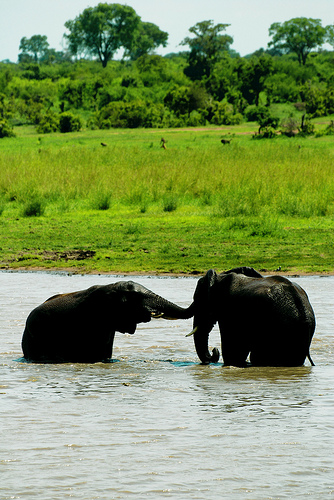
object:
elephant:
[185, 260, 321, 377]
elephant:
[17, 276, 196, 371]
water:
[0, 271, 333, 500]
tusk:
[184, 325, 198, 338]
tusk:
[150, 309, 165, 321]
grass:
[0, 125, 334, 282]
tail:
[306, 349, 316, 368]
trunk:
[191, 315, 221, 366]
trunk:
[149, 288, 197, 321]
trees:
[259, 8, 334, 72]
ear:
[190, 265, 219, 305]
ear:
[101, 288, 140, 338]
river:
[0, 266, 333, 500]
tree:
[62, 2, 168, 67]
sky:
[0, 0, 334, 64]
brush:
[14, 188, 50, 224]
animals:
[220, 135, 234, 148]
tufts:
[158, 194, 181, 217]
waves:
[0, 354, 58, 428]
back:
[229, 268, 298, 292]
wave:
[200, 365, 308, 430]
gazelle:
[98, 138, 110, 152]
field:
[0, 114, 333, 273]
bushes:
[35, 101, 85, 138]